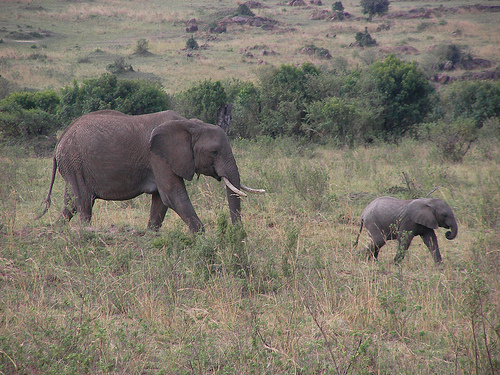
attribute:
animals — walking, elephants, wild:
[25, 86, 461, 270]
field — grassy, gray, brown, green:
[0, 136, 493, 374]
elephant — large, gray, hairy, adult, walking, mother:
[38, 108, 273, 237]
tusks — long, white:
[217, 173, 265, 199]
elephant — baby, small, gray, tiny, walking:
[348, 192, 463, 271]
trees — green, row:
[7, 59, 492, 139]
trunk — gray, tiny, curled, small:
[443, 216, 460, 242]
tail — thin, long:
[38, 152, 65, 217]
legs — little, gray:
[365, 232, 447, 269]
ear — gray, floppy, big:
[146, 125, 199, 179]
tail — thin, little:
[349, 212, 371, 251]